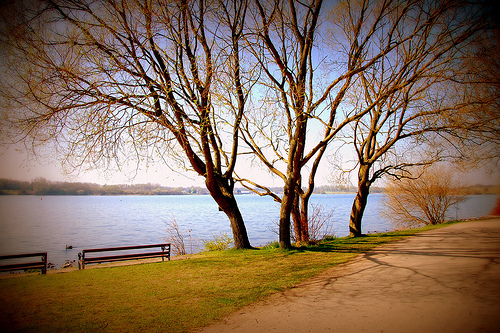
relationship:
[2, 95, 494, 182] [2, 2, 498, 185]
clouds are in sky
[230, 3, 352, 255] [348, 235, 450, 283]
tree casting shadow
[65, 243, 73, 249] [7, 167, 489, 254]
animal in water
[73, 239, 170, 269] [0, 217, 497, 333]
bench on land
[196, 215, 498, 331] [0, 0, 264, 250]
road by tree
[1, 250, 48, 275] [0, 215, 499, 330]
bench on grass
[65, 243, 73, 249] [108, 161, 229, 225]
animal on water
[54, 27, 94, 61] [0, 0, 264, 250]
leaves on tree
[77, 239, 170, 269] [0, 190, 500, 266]
bench near lake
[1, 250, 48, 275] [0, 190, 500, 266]
bench near lake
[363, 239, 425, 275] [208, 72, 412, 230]
shadow of tree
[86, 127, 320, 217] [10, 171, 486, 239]
area behind lake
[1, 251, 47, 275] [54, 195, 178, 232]
bench on side of lake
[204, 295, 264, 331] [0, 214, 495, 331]
edge of lawn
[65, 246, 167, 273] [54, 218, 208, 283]
edge of bench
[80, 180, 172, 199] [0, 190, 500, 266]
edge of lake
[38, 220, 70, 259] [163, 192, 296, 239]
animal in water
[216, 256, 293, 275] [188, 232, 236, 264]
plant by water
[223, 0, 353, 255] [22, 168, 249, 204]
tree in distance